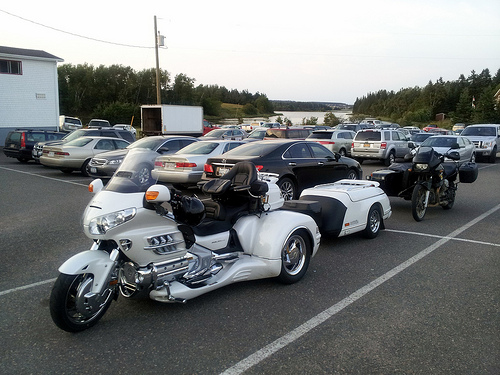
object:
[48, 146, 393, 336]
motorcycle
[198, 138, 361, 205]
car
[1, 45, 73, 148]
building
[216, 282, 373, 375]
strip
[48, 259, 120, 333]
wheel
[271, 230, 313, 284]
rear wheel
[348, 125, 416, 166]
cars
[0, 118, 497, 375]
parking lot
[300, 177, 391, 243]
trailer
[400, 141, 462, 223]
bike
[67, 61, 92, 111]
tree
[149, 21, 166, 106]
telephone pole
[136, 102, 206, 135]
trailer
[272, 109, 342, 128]
pond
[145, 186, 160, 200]
headlights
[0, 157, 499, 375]
road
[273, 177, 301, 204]
wheel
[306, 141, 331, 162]
window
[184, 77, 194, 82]
branches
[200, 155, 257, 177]
back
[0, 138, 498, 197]
ground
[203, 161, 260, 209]
seat